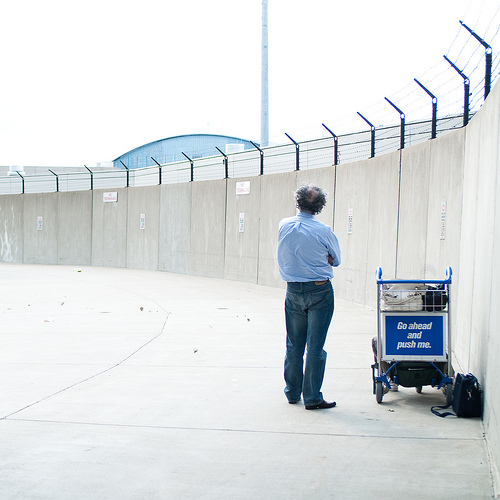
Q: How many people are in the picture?
A: One.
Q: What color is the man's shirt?
A: Blue.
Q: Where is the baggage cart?
A: Next to the man.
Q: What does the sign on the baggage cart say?
A: Go ahead and push me.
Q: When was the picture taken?
A: Daytime.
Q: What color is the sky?
A: White.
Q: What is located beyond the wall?
A: A building.